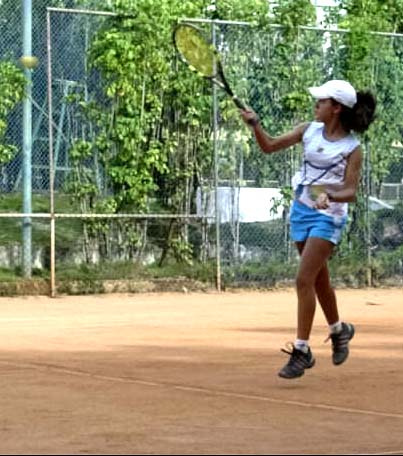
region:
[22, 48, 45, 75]
the ball is green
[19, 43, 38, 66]
the ball was hit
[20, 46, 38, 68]
the ball is in the air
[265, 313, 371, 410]
She is jumping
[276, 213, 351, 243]
her shorts are blue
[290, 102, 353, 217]
her shirt is white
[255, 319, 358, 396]
her shoes are grey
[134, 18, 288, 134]
holding racket in right hand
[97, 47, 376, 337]
she is playing tennis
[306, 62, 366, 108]
her hat is white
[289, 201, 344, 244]
light blue tennis shorts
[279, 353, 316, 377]
dark colored tennis shoe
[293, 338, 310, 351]
white sock with emblem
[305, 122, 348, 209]
white sleeveless shirt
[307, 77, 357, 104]
solid white baseball hat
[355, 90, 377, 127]
dark black curly hair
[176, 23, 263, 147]
woman holding tennis racket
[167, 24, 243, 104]
yellow and black tennis racket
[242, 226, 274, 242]
silver metal chain link fence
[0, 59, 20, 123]
bright green leaves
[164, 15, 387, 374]
the woman on the court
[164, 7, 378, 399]
the woman hitting the ball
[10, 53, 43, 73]
the ball in the air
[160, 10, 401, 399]
the woman swinging the racquet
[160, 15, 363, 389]
the woman playing tennis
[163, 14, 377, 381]
the woman is jumping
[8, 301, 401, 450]
the court is clay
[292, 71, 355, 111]
the woman wearing the hat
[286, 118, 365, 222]
woman wearing white top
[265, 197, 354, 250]
woman wearing blue shorts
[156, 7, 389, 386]
woman in white top and short shorts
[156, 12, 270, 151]
tennis racket with yellow strings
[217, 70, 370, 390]
woman jumping into the air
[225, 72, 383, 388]
woman who just hit a tennis ball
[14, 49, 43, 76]
tennis ball flying through the air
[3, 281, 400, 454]
tennis court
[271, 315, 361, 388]
sneakers and white socks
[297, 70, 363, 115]
white hat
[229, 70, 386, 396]
woman with hair tied up behind her head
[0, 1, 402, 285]
fence lining tennis court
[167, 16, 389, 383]
person holding tennis racket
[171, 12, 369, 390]
tennis player off the ground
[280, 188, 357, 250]
short light blue shorts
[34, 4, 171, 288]
chain link fence and poles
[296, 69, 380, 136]
darkhaired woman in baseball cap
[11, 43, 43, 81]
tennis ball in the air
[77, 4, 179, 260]
plant with green leaves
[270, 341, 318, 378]
shoe with laces in a bow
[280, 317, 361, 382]
pair of shoes with white stripes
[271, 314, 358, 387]
white anklet socks and shoes